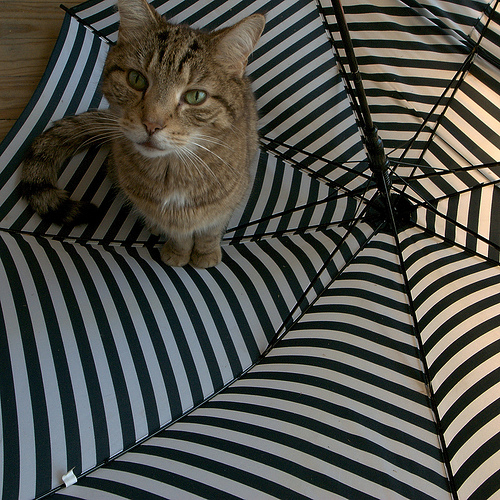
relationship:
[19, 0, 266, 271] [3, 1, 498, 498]
cat on umbrella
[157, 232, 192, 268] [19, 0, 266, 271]
paw on cat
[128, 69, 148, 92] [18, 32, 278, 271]
green eye on cat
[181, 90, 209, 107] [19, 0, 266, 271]
eye of cat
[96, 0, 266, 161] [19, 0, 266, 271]
head of cat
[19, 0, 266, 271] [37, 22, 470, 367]
cat sitting on umbrella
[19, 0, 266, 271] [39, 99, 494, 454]
cat sitting on umbrella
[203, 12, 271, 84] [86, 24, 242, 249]
ear of cat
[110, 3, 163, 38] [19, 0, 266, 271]
ear of cat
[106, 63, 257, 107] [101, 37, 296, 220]
eyeballs of cat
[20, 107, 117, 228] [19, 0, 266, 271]
tail of cat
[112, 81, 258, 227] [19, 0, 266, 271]
torso of cat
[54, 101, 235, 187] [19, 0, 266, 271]
white whiskers on cat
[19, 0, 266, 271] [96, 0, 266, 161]
cat has stripes on head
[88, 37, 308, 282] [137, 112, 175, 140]
cat has nose